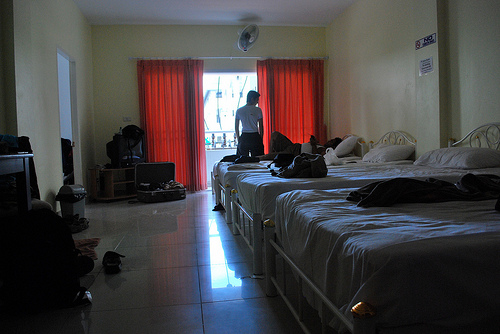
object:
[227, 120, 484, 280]
bed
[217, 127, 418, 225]
bed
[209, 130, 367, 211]
bed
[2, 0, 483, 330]
room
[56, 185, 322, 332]
floor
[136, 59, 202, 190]
curtain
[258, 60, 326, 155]
curtain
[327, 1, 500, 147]
wall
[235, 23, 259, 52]
fan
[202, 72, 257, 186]
window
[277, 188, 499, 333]
bed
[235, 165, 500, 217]
bed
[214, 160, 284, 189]
bed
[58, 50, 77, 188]
doorway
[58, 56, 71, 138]
room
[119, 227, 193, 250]
tile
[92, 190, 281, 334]
floor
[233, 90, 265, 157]
person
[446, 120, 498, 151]
headboard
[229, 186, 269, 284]
footboard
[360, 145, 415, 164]
pillow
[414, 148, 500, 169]
pillow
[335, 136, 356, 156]
pillow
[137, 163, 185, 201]
suitcase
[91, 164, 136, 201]
cabinet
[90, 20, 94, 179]
corner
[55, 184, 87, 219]
trashcan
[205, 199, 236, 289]
reflection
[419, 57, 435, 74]
picture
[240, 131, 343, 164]
man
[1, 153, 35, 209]
table